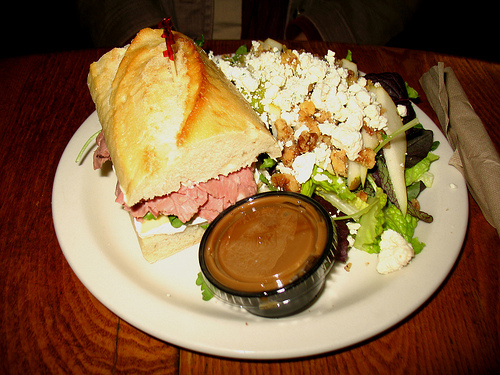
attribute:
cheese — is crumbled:
[281, 72, 402, 195]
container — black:
[206, 187, 334, 317]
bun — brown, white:
[86, 27, 278, 206]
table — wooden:
[1, 42, 498, 374]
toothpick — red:
[159, 14, 180, 77]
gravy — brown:
[193, 185, 343, 324]